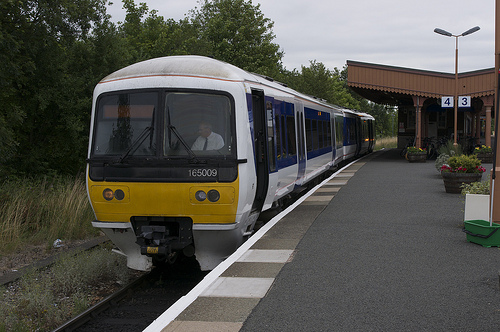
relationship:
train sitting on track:
[80, 52, 380, 275] [48, 266, 200, 329]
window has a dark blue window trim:
[249, 89, 299, 169] [265, 100, 330, 168]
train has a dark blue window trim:
[80, 52, 376, 275] [265, 100, 330, 168]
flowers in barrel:
[440, 162, 483, 172] [441, 172, 482, 189]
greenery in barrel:
[448, 155, 478, 165] [441, 172, 482, 189]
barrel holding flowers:
[441, 172, 482, 189] [440, 162, 483, 172]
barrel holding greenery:
[406, 152, 427, 159] [448, 155, 478, 165]